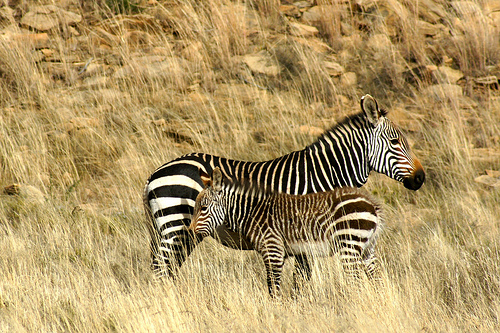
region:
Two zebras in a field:
[140, 93, 426, 293]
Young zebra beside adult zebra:
[192, 169, 387, 291]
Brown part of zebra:
[221, 177, 341, 239]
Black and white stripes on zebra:
[142, 154, 205, 276]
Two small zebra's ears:
[358, 93, 383, 124]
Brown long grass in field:
[0, 219, 499, 330]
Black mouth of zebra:
[403, 166, 425, 191]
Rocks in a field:
[1, 0, 498, 170]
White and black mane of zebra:
[308, 112, 366, 150]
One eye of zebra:
[391, 135, 403, 150]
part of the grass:
[435, 208, 447, 233]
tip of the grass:
[373, 283, 378, 289]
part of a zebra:
[292, 210, 298, 218]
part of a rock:
[120, 148, 135, 170]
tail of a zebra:
[148, 215, 154, 238]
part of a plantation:
[337, 282, 363, 300]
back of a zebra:
[361, 220, 370, 230]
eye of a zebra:
[386, 130, 409, 148]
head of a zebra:
[203, 193, 231, 215]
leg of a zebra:
[268, 273, 285, 288]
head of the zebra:
[348, 88, 433, 197]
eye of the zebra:
[378, 118, 413, 164]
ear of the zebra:
[354, 90, 389, 130]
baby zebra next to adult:
[155, 155, 390, 290]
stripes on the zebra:
[259, 199, 324, 237]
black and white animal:
[300, 135, 374, 191]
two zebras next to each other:
[118, 92, 468, 317]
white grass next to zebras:
[20, 220, 133, 324]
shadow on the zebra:
[169, 195, 190, 229]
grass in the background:
[123, 3, 326, 98]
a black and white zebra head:
[294, 92, 445, 192]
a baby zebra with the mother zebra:
[159, 180, 402, 267]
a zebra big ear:
[356, 71, 396, 126]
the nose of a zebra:
[397, 145, 454, 192]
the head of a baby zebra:
[179, 172, 267, 254]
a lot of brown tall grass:
[97, 20, 359, 159]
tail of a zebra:
[134, 167, 159, 247]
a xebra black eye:
[383, 129, 413, 154]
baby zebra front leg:
[256, 225, 304, 303]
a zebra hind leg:
[138, 131, 217, 286]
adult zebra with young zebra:
[138, 88, 429, 296]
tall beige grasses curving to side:
[31, 35, 463, 296]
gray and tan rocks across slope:
[25, 5, 485, 117]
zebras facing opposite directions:
[140, 87, 425, 292]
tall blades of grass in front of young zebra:
[186, 170, 376, 291]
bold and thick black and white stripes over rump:
[145, 151, 205, 231]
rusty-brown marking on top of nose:
[400, 145, 425, 190]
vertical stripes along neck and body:
[190, 111, 365, 191]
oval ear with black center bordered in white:
[360, 90, 380, 121]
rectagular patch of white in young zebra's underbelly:
[278, 235, 330, 251]